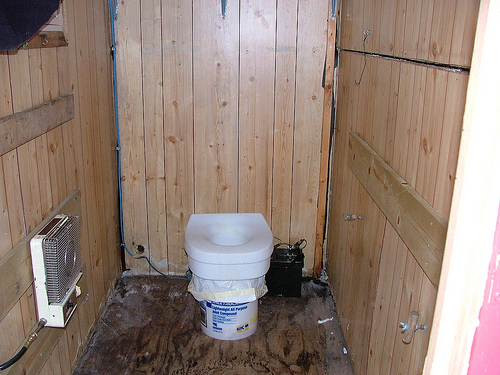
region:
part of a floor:
[166, 325, 193, 353]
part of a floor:
[173, 351, 185, 364]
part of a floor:
[168, 313, 187, 332]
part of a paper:
[228, 280, 253, 307]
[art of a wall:
[85, 274, 119, 324]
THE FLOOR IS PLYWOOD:
[61, 263, 373, 373]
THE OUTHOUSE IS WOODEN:
[1, 0, 472, 374]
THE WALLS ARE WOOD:
[2, 1, 498, 373]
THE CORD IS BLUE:
[103, 0, 196, 287]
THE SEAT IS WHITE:
[175, 200, 275, 282]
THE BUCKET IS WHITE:
[184, 260, 266, 350]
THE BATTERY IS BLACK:
[265, 240, 313, 306]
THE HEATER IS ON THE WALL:
[18, 205, 104, 340]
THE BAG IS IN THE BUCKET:
[180, 268, 271, 312]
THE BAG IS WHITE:
[179, 270, 271, 305]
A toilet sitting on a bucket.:
[160, 210, 277, 332]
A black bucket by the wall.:
[258, 232, 315, 297]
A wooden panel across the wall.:
[336, 137, 437, 257]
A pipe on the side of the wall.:
[0, 312, 44, 352]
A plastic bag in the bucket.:
[183, 268, 273, 315]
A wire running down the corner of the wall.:
[113, 137, 134, 256]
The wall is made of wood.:
[151, 49, 329, 165]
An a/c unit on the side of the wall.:
[10, 199, 103, 328]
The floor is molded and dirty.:
[314, 259, 337, 336]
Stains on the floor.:
[114, 308, 164, 370]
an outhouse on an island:
[3, 3, 498, 370]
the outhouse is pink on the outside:
[444, 206, 499, 373]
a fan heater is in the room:
[1, 201, 88, 362]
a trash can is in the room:
[266, 238, 308, 303]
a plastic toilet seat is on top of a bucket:
[182, 209, 275, 341]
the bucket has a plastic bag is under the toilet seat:
[188, 273, 268, 338]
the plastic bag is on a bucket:
[188, 270, 270, 340]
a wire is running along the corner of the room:
[102, 0, 188, 283]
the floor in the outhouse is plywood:
[90, 265, 348, 371]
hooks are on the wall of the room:
[5, 27, 72, 55]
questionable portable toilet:
[181, 207, 279, 344]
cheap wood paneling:
[117, 5, 319, 201]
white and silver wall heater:
[25, 211, 86, 333]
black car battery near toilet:
[270, 241, 309, 301]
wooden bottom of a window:
[5, 8, 66, 48]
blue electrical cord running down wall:
[110, 0, 125, 266]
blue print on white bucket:
[202, 300, 249, 335]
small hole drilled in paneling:
[131, 238, 149, 260]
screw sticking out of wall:
[341, 210, 361, 225]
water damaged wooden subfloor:
[100, 315, 319, 373]